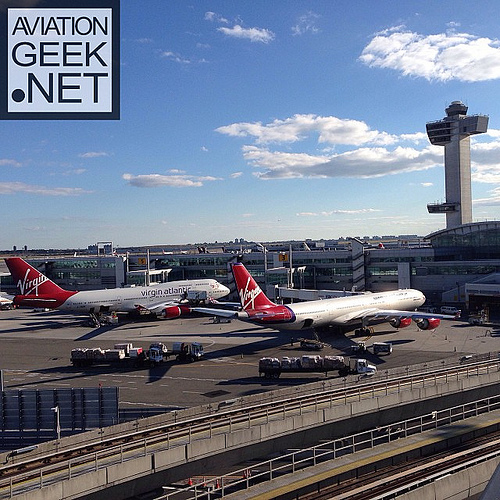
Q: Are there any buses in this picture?
A: No, there are no buses.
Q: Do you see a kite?
A: No, there are no kites.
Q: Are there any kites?
A: No, there are no kites.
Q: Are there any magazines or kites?
A: No, there are no kites or magazines.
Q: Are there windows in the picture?
A: Yes, there are windows.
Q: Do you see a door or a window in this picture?
A: Yes, there are windows.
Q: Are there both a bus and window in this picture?
A: No, there are windows but no buses.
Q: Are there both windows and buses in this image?
A: No, there are windows but no buses.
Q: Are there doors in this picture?
A: No, there are no doors.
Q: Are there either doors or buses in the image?
A: No, there are no doors or buses.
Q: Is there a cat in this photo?
A: No, there are no cats.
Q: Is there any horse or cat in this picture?
A: No, there are no cats or horses.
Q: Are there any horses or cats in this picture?
A: No, there are no cats or horses.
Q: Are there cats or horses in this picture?
A: No, there are no cats or horses.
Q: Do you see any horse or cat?
A: No, there are no cats or horses.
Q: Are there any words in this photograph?
A: Yes, there are words.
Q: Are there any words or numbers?
A: Yes, there are words.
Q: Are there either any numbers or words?
A: Yes, there are words.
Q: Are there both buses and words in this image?
A: No, there are words but no buses.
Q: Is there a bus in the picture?
A: No, there are no buses.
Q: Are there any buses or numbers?
A: No, there are no buses or numbers.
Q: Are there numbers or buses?
A: No, there are no buses or numbers.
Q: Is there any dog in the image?
A: No, there are no dogs.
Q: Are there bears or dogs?
A: No, there are no dogs or bears.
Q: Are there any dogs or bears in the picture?
A: No, there are no dogs or bears.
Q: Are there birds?
A: No, there are no birds.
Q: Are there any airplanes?
A: Yes, there is an airplane.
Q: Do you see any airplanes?
A: Yes, there is an airplane.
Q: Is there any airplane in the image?
A: Yes, there is an airplane.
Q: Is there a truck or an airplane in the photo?
A: Yes, there is an airplane.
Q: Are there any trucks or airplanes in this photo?
A: Yes, there is an airplane.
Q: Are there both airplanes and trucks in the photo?
A: Yes, there are both an airplane and a truck.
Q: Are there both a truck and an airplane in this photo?
A: Yes, there are both an airplane and a truck.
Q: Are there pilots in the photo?
A: No, there are no pilots.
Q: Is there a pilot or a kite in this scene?
A: No, there are no pilots or kites.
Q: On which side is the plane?
A: The plane is on the left of the image.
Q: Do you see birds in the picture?
A: No, there are no birds.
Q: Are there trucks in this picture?
A: Yes, there is a truck.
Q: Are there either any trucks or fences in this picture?
A: Yes, there is a truck.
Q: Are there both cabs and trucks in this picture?
A: No, there is a truck but no taxis.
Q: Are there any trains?
A: No, there are no trains.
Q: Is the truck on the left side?
A: Yes, the truck is on the left of the image.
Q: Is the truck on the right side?
A: No, the truck is on the left of the image.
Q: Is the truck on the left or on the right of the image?
A: The truck is on the left of the image.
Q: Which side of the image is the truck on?
A: The truck is on the left of the image.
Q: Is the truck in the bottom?
A: Yes, the truck is in the bottom of the image.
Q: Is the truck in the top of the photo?
A: No, the truck is in the bottom of the image.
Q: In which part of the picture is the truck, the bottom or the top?
A: The truck is in the bottom of the image.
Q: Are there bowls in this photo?
A: No, there are no bowls.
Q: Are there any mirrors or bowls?
A: No, there are no bowls or mirrors.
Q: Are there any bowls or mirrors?
A: No, there are no bowls or mirrors.